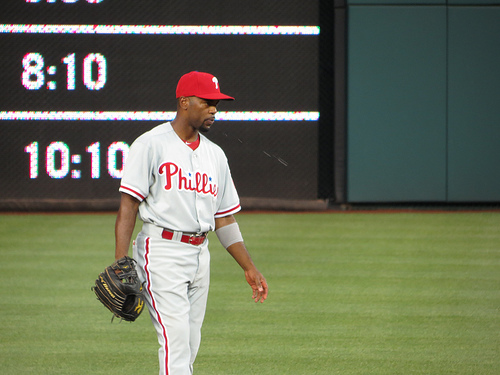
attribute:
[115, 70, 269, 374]
man — phillies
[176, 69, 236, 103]
cap — red, beautiful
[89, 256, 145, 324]
glove — black, leather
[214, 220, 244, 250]
band — grey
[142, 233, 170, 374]
stripe — red, vertical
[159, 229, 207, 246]
belt — red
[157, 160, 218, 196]
team name — red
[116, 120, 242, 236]
jersey — white, red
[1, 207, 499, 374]
field — green, grass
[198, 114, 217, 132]
facial hair — black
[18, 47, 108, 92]
time — white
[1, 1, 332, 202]
scoreboard — black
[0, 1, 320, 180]
lights — white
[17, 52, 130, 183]
numbers — white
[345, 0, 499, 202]
wall — blue